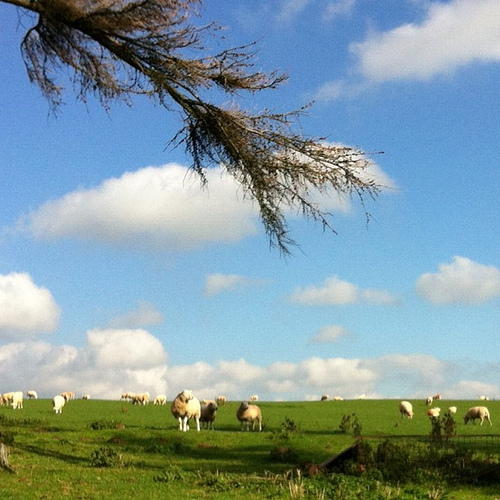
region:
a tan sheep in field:
[172, 390, 201, 431]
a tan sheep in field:
[236, 398, 263, 432]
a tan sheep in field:
[198, 397, 216, 427]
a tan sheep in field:
[49, 390, 65, 412]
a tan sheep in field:
[60, 388, 73, 400]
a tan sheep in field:
[130, 393, 146, 403]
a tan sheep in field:
[399, 397, 413, 416]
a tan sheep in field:
[427, 404, 439, 416]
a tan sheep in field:
[462, 405, 489, 425]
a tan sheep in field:
[425, 393, 434, 404]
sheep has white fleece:
[14, 392, 24, 412]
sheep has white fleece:
[51, 398, 66, 420]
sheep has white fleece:
[132, 394, 147, 405]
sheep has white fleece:
[154, 397, 166, 407]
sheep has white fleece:
[175, 394, 204, 434]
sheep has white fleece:
[202, 399, 219, 426]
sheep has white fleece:
[236, 404, 263, 429]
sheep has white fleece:
[396, 402, 421, 422]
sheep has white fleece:
[429, 407, 441, 421]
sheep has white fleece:
[465, 409, 490, 426]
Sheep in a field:
[107, 370, 289, 455]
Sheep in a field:
[401, 388, 493, 422]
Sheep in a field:
[52, 383, 88, 420]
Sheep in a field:
[311, 384, 373, 419]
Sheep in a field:
[120, 386, 173, 411]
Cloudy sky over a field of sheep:
[32, 306, 197, 388]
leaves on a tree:
[129, 45, 358, 239]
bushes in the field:
[318, 415, 446, 482]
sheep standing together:
[18, 380, 135, 420]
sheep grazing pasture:
[398, 398, 420, 418]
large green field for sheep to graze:
[10, 385, 492, 482]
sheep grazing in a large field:
[20, 358, 481, 487]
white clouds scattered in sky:
[22, 143, 490, 365]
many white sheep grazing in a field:
[10, 360, 490, 476]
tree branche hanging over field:
[14, 8, 381, 253]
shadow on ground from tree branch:
[105, 420, 467, 481]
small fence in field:
[349, 428, 499, 475]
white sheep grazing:
[19, 378, 496, 427]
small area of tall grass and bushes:
[282, 445, 489, 496]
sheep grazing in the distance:
[312, 383, 362, 403]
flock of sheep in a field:
[67, 369, 364, 448]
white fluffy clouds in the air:
[91, 198, 198, 339]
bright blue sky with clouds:
[94, 224, 161, 309]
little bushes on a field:
[79, 410, 134, 495]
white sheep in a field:
[152, 387, 265, 437]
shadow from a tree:
[269, 430, 468, 490]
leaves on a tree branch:
[233, 132, 288, 188]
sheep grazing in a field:
[374, 382, 483, 449]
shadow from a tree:
[10, 431, 112, 480]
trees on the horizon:
[42, 337, 427, 402]